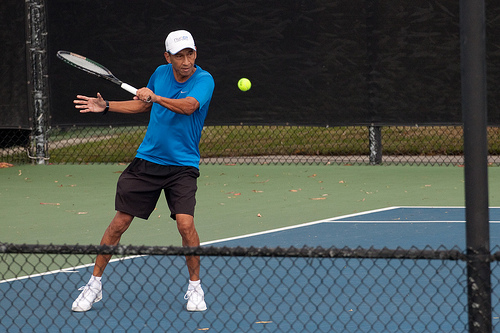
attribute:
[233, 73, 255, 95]
ball — neon, green, yellow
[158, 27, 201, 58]
hat — white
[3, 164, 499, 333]
tennis court — blue, green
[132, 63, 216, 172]
shirt — blue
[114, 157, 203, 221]
shorts — black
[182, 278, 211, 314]
shoe — white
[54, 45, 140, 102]
racket — black, white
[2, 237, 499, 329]
fence — chained link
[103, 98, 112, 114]
wristwatch — black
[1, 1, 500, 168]
fence — chain link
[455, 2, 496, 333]
pole — tall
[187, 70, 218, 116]
sleeve — short